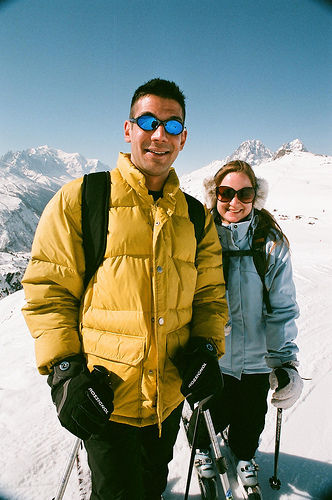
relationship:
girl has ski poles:
[193, 157, 306, 499] [258, 380, 288, 494]